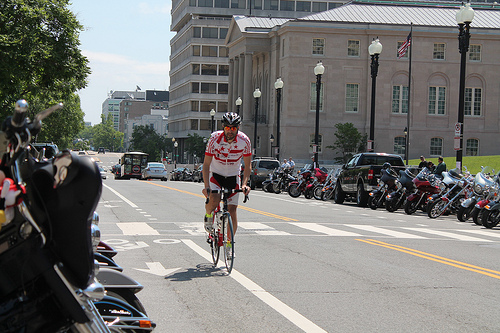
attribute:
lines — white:
[218, 279, 310, 321]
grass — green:
[388, 150, 498, 185]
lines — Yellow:
[353, 236, 498, 281]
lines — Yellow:
[139, 175, 293, 221]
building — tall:
[177, 19, 242, 163]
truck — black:
[331, 128, 437, 232]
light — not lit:
[452, 11, 472, 171]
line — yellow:
[131, 180, 499, 281]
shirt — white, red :
[206, 130, 253, 177]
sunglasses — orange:
[221, 124, 243, 131]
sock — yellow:
[202, 212, 216, 219]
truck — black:
[331, 150, 416, 230]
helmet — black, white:
[219, 110, 243, 125]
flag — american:
[390, 33, 415, 60]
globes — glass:
[269, 3, 476, 88]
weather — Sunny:
[79, 6, 185, 116]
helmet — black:
[220, 113, 240, 129]